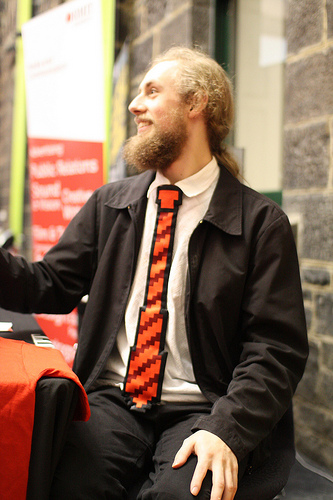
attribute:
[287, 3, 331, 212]
wall — brick, grey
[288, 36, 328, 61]
line — white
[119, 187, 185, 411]
tie — orange, red, long, black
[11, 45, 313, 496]
man — black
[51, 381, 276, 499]
pants — black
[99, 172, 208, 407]
shirt — white, short sleeved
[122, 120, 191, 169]
beard — brown, trimmed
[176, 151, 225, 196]
collar — white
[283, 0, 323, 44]
brick — grey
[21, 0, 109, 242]
sign — red, white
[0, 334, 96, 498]
shirt — orange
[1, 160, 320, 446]
jacket — black